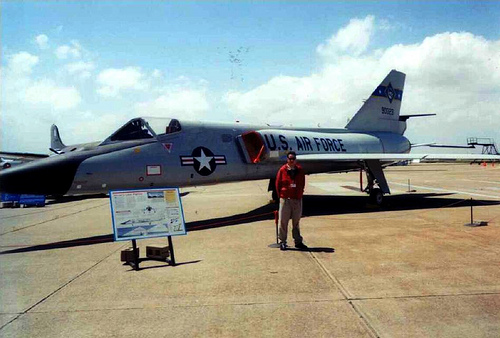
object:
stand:
[126, 235, 176, 271]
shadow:
[0, 185, 500, 255]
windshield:
[110, 117, 155, 142]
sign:
[110, 188, 188, 241]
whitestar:
[193, 149, 215, 172]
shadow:
[266, 242, 332, 252]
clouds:
[32, 34, 51, 51]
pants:
[276, 196, 302, 245]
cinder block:
[119, 245, 139, 263]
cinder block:
[145, 245, 173, 262]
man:
[273, 151, 308, 251]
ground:
[1, 162, 500, 337]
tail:
[343, 69, 406, 134]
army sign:
[179, 144, 227, 177]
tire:
[365, 187, 384, 202]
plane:
[14, 63, 434, 206]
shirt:
[274, 163, 306, 199]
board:
[110, 187, 187, 241]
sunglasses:
[286, 155, 297, 160]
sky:
[0, 1, 500, 160]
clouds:
[93, 64, 141, 99]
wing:
[290, 152, 498, 160]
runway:
[1, 160, 497, 334]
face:
[287, 154, 297, 165]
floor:
[1, 162, 500, 337]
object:
[466, 193, 486, 227]